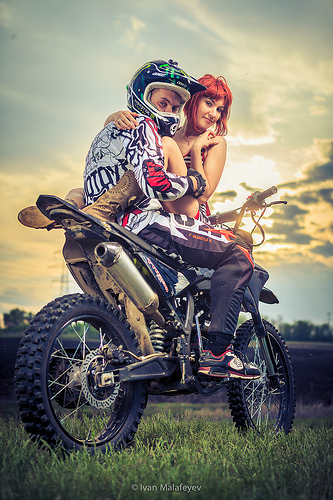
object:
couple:
[17, 58, 263, 380]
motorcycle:
[15, 185, 297, 456]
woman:
[161, 72, 234, 223]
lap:
[144, 209, 258, 271]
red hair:
[204, 72, 233, 97]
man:
[83, 46, 207, 262]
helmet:
[125, 58, 207, 139]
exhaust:
[93, 240, 164, 328]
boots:
[18, 167, 141, 232]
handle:
[252, 185, 279, 208]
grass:
[0, 389, 323, 499]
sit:
[35, 193, 188, 281]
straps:
[89, 188, 133, 219]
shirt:
[82, 111, 188, 230]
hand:
[101, 108, 140, 132]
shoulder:
[84, 106, 160, 147]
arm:
[189, 128, 227, 205]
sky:
[0, 15, 126, 110]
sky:
[234, 33, 332, 176]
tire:
[13, 291, 151, 464]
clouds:
[232, 5, 332, 263]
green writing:
[159, 59, 184, 83]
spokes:
[47, 322, 129, 444]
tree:
[5, 305, 26, 332]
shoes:
[16, 168, 144, 233]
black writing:
[83, 158, 114, 188]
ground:
[0, 330, 331, 497]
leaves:
[5, 310, 25, 326]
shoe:
[197, 344, 262, 381]